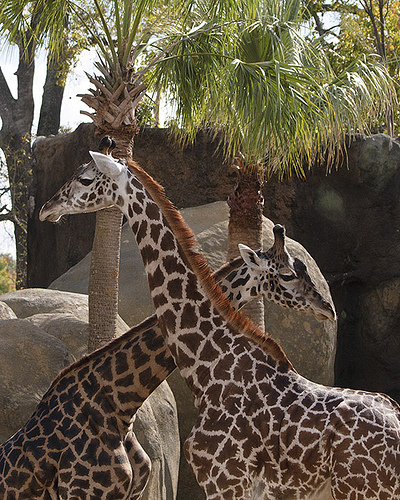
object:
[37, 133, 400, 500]
giraffe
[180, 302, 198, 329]
spots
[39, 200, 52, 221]
nose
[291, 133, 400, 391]
boulders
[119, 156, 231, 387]
long neck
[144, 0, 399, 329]
tree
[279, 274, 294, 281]
right eye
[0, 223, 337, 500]
giraffe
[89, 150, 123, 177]
left ear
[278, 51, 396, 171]
leaves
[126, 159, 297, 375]
mane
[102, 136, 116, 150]
black knobs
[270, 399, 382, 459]
white lines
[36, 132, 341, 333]
opposite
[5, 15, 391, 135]
sky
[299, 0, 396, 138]
trees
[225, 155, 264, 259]
bark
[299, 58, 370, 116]
stems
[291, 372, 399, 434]
back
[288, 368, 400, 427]
reflection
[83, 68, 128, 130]
treetops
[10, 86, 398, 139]
horizon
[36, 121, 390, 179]
shadows